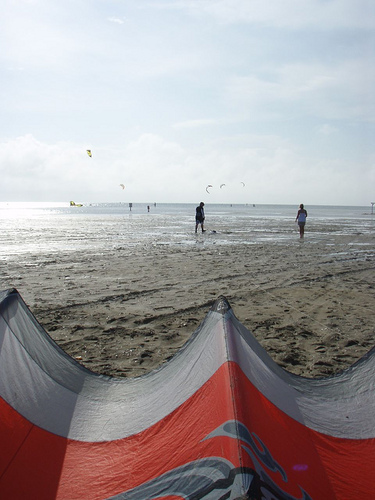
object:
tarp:
[0, 285, 375, 500]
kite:
[240, 182, 245, 189]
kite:
[84, 149, 93, 159]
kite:
[119, 184, 126, 190]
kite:
[205, 184, 212, 195]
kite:
[220, 184, 227, 189]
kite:
[241, 181, 245, 187]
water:
[0, 203, 374, 251]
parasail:
[119, 183, 125, 189]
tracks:
[0, 238, 375, 379]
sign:
[147, 205, 150, 212]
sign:
[154, 202, 157, 206]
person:
[147, 204, 150, 212]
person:
[129, 202, 132, 210]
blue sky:
[0, 0, 373, 206]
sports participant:
[71, 197, 85, 209]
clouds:
[0, 0, 375, 104]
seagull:
[241, 180, 246, 186]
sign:
[128, 202, 132, 211]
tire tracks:
[0, 251, 373, 380]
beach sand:
[2, 205, 373, 383]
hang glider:
[0, 285, 375, 500]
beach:
[0, 207, 374, 375]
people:
[294, 202, 308, 238]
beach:
[1, 202, 374, 380]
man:
[194, 201, 206, 234]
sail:
[0, 291, 374, 500]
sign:
[125, 199, 137, 213]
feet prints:
[0, 251, 375, 378]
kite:
[69, 200, 83, 207]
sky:
[0, 0, 375, 206]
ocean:
[0, 202, 375, 249]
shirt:
[296, 208, 308, 225]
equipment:
[70, 201, 82, 208]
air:
[0, 0, 374, 203]